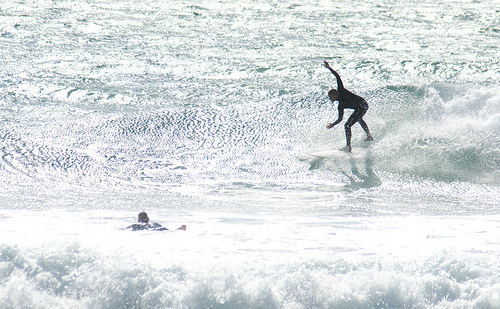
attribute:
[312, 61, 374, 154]
man — surfing, barefoot, falling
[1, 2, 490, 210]
water — calm, spraying, foamy, white, blue, grey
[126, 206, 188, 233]
person — flat, lying down, swimming, lying flat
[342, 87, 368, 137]
wetsuit — black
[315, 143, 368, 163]
surfboard — white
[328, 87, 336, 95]
hair — short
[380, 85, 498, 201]
wave — foamy, white, cresting, rising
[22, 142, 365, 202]
ripples — dark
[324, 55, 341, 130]
arms — raised, out to the side, bent